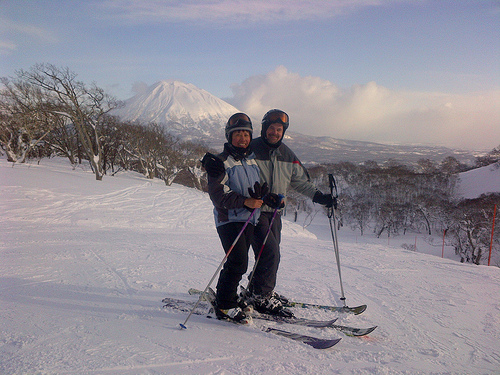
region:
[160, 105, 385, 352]
The people shown skiing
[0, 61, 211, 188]
Barren trees behind the couple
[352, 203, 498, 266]
Orange poles sticking out of the ground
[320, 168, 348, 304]
Poles in the man's left hand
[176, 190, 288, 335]
Poles the woman is holding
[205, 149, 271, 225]
Black and blue jacket of the woman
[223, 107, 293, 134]
Goggles of the people shown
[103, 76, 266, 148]
Mountain peak shown in the background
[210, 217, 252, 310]
The woman's pants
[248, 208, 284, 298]
The man's pants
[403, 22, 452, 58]
a patch of blue sky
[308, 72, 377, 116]
a white cloud in the sky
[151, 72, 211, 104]
snow on a mountain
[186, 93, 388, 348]
people on skis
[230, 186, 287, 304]
a person holding ski poles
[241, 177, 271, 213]
a person holding a black glove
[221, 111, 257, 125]
black ski goggles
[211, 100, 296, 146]
people wearing ski helmets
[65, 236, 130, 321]
tracks on a ski trail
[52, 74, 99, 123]
a tree without leaves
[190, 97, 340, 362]
two people posing while standing on snow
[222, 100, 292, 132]
both people have goggles pushed up onto their helmets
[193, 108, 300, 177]
man's arm around woman's shoulder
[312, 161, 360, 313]
man holding two ski poles with his left hand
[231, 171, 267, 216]
woman holding glove in her right hand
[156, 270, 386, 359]
both people are wearing skis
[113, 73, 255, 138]
snow capped mountain in the distance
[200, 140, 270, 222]
woman wearing blue, white, and black jacket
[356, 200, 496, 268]
red poles stuck in snow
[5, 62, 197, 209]
leafless trees in background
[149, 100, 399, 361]
Two people standing on snow skis.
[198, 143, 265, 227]
Woman wearing blue, gray and white jacket.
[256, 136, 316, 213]
Man wearing light gray and dark gray jacket.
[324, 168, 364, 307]
Man holding ski poles in one hand.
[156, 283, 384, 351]
Two pairs of snow skis.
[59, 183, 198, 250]
Ski tracks in snow.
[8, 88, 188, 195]
Bare trees growing on mountain top.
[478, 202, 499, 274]
Red pole in snow.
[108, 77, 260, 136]
Snow covered mountain in distance.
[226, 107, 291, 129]
Both people wearing orange goggles.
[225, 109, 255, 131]
Snow goggles on woman's head.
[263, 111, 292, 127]
Snow goggles on man's head.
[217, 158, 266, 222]
Blue jacket worn by the woman.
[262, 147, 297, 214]
Gray jacket worn by the man.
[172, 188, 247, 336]
Ski pole in the woman's left hand.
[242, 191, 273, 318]
Ski pole in the woman's right hand.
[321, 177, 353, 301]
Ski pole in the man's right hand.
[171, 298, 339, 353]
Skis worn by the woman.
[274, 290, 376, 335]
Skis worn by the man.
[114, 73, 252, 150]
Snow covered mountain in the background.